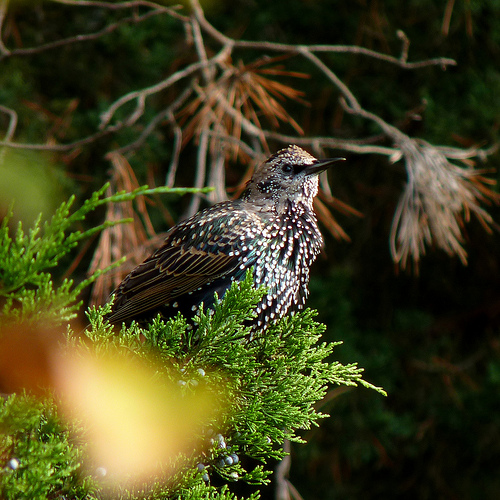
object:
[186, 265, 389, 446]
leaves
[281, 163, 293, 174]
eye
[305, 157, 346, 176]
beak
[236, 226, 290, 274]
dots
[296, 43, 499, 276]
branch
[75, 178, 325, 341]
feather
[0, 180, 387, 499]
tree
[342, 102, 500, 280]
flower